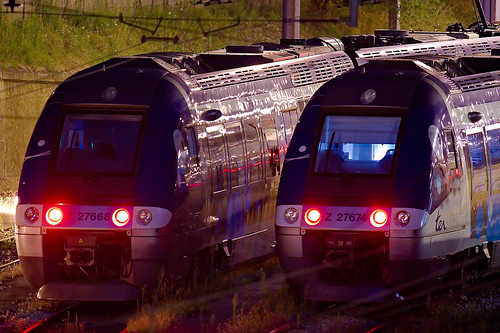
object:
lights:
[371, 143, 395, 161]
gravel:
[409, 290, 499, 329]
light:
[301, 209, 322, 226]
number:
[338, 213, 367, 223]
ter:
[431, 205, 456, 235]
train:
[11, 20, 500, 310]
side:
[428, 85, 497, 247]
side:
[176, 74, 278, 254]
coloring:
[221, 183, 256, 233]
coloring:
[471, 130, 499, 162]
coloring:
[473, 197, 498, 234]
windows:
[305, 109, 416, 183]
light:
[368, 209, 387, 228]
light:
[111, 207, 129, 227]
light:
[25, 207, 40, 223]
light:
[136, 208, 153, 226]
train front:
[275, 58, 442, 291]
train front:
[13, 57, 207, 304]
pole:
[281, 3, 306, 36]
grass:
[127, 263, 306, 331]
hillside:
[4, 0, 497, 80]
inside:
[70, 117, 132, 168]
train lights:
[46, 208, 62, 227]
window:
[441, 122, 455, 155]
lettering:
[435, 210, 447, 231]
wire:
[16, 8, 348, 35]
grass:
[0, 65, 53, 246]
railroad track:
[0, 236, 499, 333]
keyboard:
[10, 42, 266, 320]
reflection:
[188, 131, 279, 183]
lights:
[282, 206, 299, 224]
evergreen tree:
[5, 42, 230, 309]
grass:
[0, 0, 477, 59]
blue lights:
[321, 142, 396, 173]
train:
[271, 53, 499, 305]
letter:
[325, 212, 332, 221]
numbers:
[78, 212, 110, 221]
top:
[160, 47, 277, 77]